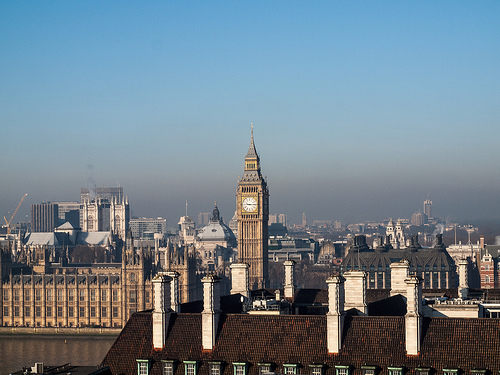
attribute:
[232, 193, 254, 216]
clock — white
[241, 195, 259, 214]
clock — round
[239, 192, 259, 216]
clock — circle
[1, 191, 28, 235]
construction crane — metal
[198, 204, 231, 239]
dome — Green 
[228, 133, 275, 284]
tower — tall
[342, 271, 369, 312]
chimney — brick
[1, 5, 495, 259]
sky — hazy